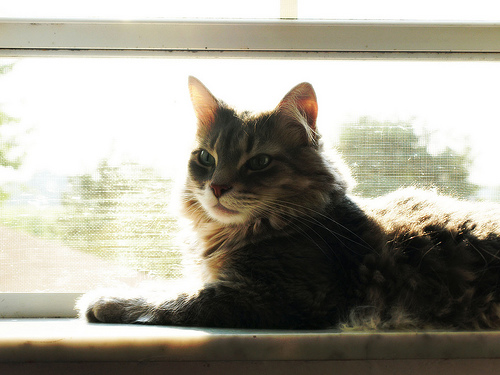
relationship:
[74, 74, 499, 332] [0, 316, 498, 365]
cat sitting in window sill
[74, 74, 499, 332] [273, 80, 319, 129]
cat has ear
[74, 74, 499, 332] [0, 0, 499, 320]
cat sitting in window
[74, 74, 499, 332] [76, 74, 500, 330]
cat has fur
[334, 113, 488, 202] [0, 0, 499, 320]
tree seen outside window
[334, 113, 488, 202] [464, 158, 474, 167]
tree has leaf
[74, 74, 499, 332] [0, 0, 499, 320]
cat laying in window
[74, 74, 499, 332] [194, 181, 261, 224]
cat has muzzle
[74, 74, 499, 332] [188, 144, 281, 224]
cat has face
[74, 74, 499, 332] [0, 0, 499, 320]
cat sits in window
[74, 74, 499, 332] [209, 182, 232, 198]
cat has nose